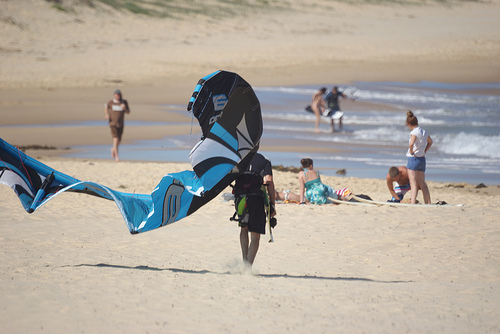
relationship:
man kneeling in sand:
[386, 166, 411, 203] [0, 2, 500, 332]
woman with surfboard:
[311, 88, 327, 127] [306, 106, 343, 119]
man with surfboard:
[327, 87, 356, 132] [306, 107, 344, 118]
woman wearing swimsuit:
[297, 156, 354, 203] [303, 168, 329, 202]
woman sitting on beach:
[297, 156, 354, 203] [2, 3, 498, 332]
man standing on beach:
[226, 137, 275, 270] [2, 3, 498, 332]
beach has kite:
[2, 3, 498, 332] [1, 66, 261, 235]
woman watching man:
[403, 110, 433, 205] [385, 167, 415, 202]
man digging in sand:
[385, 167, 415, 202] [3, 162, 497, 330]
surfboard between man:
[303, 105, 342, 118] [322, 85, 347, 134]